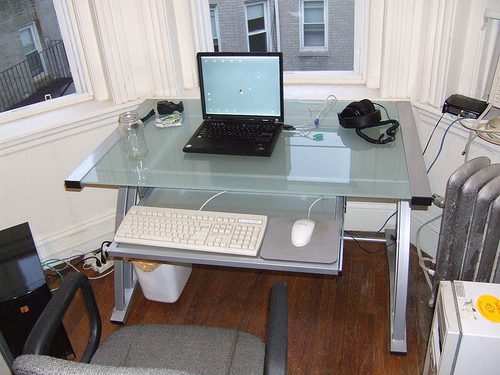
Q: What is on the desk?
A: Keyboard.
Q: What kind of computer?
A: Laptop.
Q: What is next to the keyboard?
A: Mouse.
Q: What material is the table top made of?
A: Glass.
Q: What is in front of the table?
A: A chair.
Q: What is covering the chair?
A: Cloth.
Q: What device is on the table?
A: A laptop.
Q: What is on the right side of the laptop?
A: Headphones.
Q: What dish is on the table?
A: A glass.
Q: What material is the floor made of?
A: Wood.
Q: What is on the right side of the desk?
A: A radiator.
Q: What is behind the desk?
A: Windows.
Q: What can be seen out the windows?
A: Building.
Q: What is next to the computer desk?
A: An old fashioned radiator.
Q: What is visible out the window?
A: A building.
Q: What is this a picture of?
A: A stark and functional desk.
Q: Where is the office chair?
A: On a wooden floor.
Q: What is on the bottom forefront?
A: Part of gray desk chair.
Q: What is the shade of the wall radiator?
A: Silver.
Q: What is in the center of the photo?
A: The glass desk the laptop is on.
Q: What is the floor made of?
A: Wood.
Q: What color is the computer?
A: Black.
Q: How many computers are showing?
A: One.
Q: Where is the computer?
A: The desk.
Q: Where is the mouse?
A: Next to keyboard.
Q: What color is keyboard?
A: White.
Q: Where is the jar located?
A: The desk.